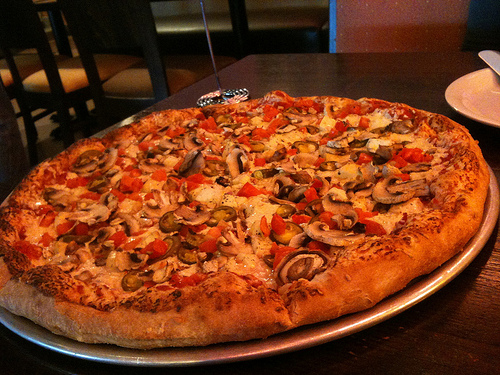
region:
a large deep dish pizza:
[0, 91, 490, 348]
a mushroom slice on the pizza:
[274, 250, 327, 280]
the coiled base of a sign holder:
[199, 88, 249, 103]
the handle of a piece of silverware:
[477, 46, 498, 76]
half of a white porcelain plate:
[440, 68, 498, 128]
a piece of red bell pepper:
[239, 184, 259, 196]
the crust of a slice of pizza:
[2, 275, 286, 348]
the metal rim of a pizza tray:
[4, 153, 498, 365]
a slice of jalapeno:
[207, 206, 239, 226]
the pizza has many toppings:
[8, 103, 484, 332]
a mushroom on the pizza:
[277, 250, 324, 291]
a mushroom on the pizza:
[376, 178, 426, 203]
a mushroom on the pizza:
[180, 206, 205, 224]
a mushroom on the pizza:
[226, 152, 257, 175]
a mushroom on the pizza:
[96, 148, 113, 171]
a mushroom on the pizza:
[162, 137, 182, 157]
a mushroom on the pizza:
[115, 209, 140, 238]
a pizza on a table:
[47, 18, 496, 360]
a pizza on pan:
[114, 51, 449, 368]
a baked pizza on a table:
[22, 37, 494, 326]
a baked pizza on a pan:
[67, 88, 499, 358]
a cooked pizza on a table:
[47, 56, 496, 364]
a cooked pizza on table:
[42, 76, 462, 374]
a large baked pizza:
[104, 62, 489, 351]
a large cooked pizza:
[80, 83, 440, 362]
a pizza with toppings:
[84, 70, 367, 298]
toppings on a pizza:
[73, 57, 483, 332]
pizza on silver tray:
[30, 130, 412, 294]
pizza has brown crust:
[68, 127, 423, 308]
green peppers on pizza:
[124, 172, 239, 252]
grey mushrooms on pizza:
[260, 191, 425, 312]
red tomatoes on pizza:
[208, 166, 335, 281]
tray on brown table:
[224, 53, 476, 355]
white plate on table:
[432, 59, 499, 133]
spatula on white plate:
[459, 54, 498, 79]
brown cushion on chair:
[12, 5, 129, 131]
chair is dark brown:
[42, 20, 164, 113]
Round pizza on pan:
[5, 95, 490, 341]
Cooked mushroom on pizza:
[275, 251, 335, 277]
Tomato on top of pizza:
[238, 183, 263, 198]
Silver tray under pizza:
[2, 173, 497, 373]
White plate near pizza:
[445, 65, 498, 124]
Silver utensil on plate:
[480, 49, 498, 72]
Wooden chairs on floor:
[0, 0, 105, 146]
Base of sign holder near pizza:
[192, 82, 255, 108]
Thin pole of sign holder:
[197, 3, 226, 95]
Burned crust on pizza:
[92, 281, 282, 336]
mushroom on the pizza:
[281, 250, 321, 283]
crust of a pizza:
[298, 244, 412, 319]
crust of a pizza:
[57, 303, 174, 345]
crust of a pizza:
[453, 130, 485, 217]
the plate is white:
[445, 63, 498, 122]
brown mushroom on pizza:
[270, 249, 340, 287]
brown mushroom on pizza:
[273, 248, 338, 280]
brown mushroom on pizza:
[269, 245, 331, 285]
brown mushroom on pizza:
[271, 240, 335, 283]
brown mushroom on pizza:
[261, 237, 335, 296]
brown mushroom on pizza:
[266, 239, 334, 289]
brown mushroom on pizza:
[264, 245, 339, 292]